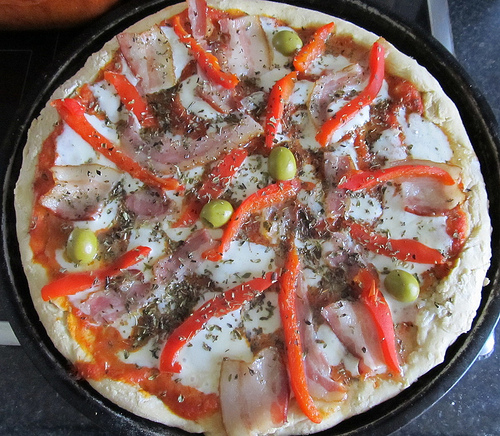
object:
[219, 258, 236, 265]
seasonings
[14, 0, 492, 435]
pizza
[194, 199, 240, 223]
olives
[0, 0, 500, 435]
tray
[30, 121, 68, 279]
sauce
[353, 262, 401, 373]
pepper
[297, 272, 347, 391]
bacon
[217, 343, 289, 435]
bacon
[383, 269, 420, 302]
vegetable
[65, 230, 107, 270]
olive